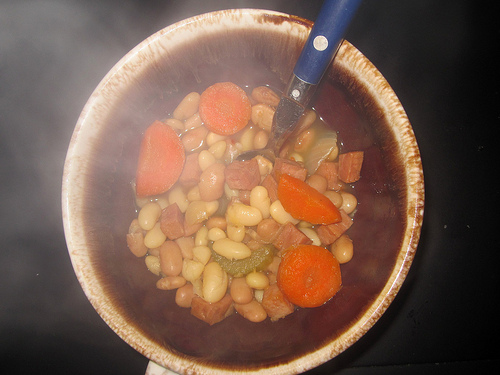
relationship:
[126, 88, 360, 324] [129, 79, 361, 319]
beans and carrot stew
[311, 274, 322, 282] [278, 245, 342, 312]
piece of caroot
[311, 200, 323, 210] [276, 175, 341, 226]
piece of caroot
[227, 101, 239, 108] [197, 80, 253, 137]
piece of caroot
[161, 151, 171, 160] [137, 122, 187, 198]
piece of caroot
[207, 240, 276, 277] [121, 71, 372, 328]
green vegetable in soup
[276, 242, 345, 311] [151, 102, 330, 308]
carrot in soup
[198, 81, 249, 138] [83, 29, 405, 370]
carrot in soup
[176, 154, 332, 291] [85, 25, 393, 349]
vegetable in soup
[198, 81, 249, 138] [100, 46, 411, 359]
carrot in soup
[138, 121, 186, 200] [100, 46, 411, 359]
carrot in soup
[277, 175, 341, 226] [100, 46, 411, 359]
carrot in soup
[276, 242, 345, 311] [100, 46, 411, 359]
carrot in soup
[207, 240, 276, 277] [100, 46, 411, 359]
green vegetable in soup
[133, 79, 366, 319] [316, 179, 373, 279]
vegetable in soup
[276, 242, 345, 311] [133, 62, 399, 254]
carrot in soup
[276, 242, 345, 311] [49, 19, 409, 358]
carrot in soup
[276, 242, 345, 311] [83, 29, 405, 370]
carrot in soup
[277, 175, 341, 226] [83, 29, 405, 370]
carrot in soup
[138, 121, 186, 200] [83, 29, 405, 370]
carrot in soup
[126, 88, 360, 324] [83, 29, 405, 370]
beans in soup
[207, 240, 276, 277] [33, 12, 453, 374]
green vegetable in soup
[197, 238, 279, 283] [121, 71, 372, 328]
green vegetable in soup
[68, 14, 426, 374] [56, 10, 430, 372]
soup in bowl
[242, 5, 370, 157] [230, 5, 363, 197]
handle on spoon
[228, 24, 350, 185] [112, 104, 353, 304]
spoon in soup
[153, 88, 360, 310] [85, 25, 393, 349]
beans in soup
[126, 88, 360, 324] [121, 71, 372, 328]
beans in soup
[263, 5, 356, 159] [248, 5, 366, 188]
handle of spoon